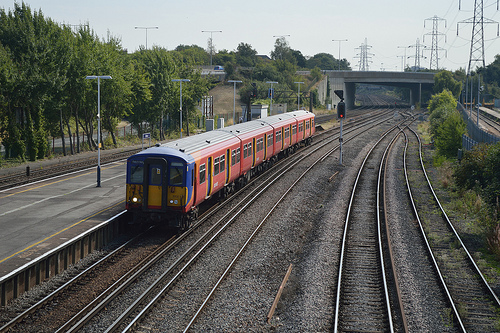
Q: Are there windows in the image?
A: Yes, there is a window.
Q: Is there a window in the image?
A: Yes, there is a window.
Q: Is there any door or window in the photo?
A: Yes, there is a window.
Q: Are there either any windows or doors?
A: Yes, there is a window.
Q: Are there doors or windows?
A: Yes, there is a window.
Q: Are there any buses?
A: No, there are no buses.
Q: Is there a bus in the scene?
A: No, there are no buses.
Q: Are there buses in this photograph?
A: No, there are no buses.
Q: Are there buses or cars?
A: No, there are no buses or cars.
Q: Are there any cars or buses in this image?
A: No, there are no buses or cars.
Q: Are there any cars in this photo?
A: No, there are no cars.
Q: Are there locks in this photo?
A: No, there are no locks.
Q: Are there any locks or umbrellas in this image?
A: No, there are no locks or umbrellas.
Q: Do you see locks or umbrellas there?
A: No, there are no locks or umbrellas.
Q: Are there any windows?
A: Yes, there is a window.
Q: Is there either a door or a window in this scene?
A: Yes, there is a window.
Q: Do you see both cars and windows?
A: No, there is a window but no cars.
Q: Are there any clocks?
A: No, there are no clocks.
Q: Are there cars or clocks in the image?
A: No, there are no clocks or cars.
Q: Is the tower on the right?
A: Yes, the tower is on the right of the image.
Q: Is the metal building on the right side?
A: Yes, the tower is on the right of the image.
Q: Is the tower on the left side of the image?
A: No, the tower is on the right of the image.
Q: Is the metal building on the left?
A: No, the tower is on the right of the image.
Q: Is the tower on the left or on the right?
A: The tower is on the right of the image.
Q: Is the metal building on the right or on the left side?
A: The tower is on the right of the image.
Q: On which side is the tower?
A: The tower is on the right of the image.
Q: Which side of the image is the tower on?
A: The tower is on the right of the image.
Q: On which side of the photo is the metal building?
A: The tower is on the right of the image.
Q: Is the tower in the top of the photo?
A: Yes, the tower is in the top of the image.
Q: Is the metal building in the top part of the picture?
A: Yes, the tower is in the top of the image.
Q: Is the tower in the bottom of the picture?
A: No, the tower is in the top of the image.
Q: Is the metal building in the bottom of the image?
A: No, the tower is in the top of the image.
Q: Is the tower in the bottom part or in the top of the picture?
A: The tower is in the top of the image.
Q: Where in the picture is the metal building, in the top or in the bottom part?
A: The tower is in the top of the image.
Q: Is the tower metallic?
A: Yes, the tower is metallic.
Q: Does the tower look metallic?
A: Yes, the tower is metallic.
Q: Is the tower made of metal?
A: Yes, the tower is made of metal.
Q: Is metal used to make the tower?
A: Yes, the tower is made of metal.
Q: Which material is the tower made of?
A: The tower is made of metal.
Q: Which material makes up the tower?
A: The tower is made of metal.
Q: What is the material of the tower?
A: The tower is made of metal.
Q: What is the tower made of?
A: The tower is made of metal.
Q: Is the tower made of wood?
A: No, the tower is made of metal.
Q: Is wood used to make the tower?
A: No, the tower is made of metal.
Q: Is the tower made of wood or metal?
A: The tower is made of metal.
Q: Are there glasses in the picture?
A: No, there are no glasses.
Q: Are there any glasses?
A: No, there are no glasses.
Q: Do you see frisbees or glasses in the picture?
A: No, there are no glasses or frisbees.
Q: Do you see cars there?
A: No, there are no cars.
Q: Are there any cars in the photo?
A: No, there are no cars.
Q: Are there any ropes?
A: No, there are no ropes.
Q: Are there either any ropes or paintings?
A: No, there are no ropes or paintings.